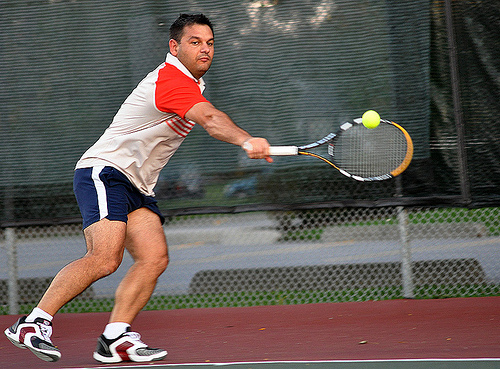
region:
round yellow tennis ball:
[350, 102, 384, 141]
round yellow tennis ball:
[358, 109, 383, 133]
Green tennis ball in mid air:
[366, 83, 401, 139]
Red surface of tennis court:
[5, 278, 498, 341]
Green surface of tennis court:
[199, 347, 489, 367]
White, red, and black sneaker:
[77, 311, 171, 364]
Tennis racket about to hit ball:
[266, 96, 488, 177]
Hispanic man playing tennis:
[63, 32, 318, 360]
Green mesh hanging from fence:
[2, 10, 483, 263]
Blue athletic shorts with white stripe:
[69, 154, 195, 235]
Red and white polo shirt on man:
[101, 62, 263, 195]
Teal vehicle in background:
[223, 153, 285, 215]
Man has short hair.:
[168, 21, 233, 51]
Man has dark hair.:
[166, 26, 206, 47]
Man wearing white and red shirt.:
[155, 100, 207, 167]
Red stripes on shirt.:
[168, 111, 203, 138]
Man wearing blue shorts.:
[81, 157, 158, 242]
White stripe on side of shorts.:
[83, 171, 160, 246]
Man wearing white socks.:
[28, 295, 146, 337]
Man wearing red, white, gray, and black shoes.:
[22, 311, 155, 353]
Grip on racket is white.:
[257, 120, 313, 208]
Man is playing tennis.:
[75, 25, 404, 263]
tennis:
[8, 5, 485, 365]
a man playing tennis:
[7, 5, 425, 362]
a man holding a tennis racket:
[8, 5, 419, 363]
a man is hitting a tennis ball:
[1, 9, 416, 362]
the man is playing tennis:
[14, 7, 423, 362]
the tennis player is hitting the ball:
[16, 17, 419, 363]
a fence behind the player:
[5, 5, 498, 312]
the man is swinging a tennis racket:
[17, 8, 419, 361]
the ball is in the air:
[358, 104, 386, 144]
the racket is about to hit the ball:
[243, 101, 428, 213]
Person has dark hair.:
[169, 13, 241, 56]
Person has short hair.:
[162, 16, 244, 42]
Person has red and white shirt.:
[123, 65, 190, 151]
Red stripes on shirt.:
[166, 105, 213, 148]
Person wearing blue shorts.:
[63, 179, 132, 215]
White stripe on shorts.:
[67, 165, 151, 257]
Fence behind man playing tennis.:
[242, 184, 317, 311]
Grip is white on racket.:
[248, 113, 303, 198]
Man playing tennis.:
[161, 93, 393, 235]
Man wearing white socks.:
[21, 307, 192, 331]